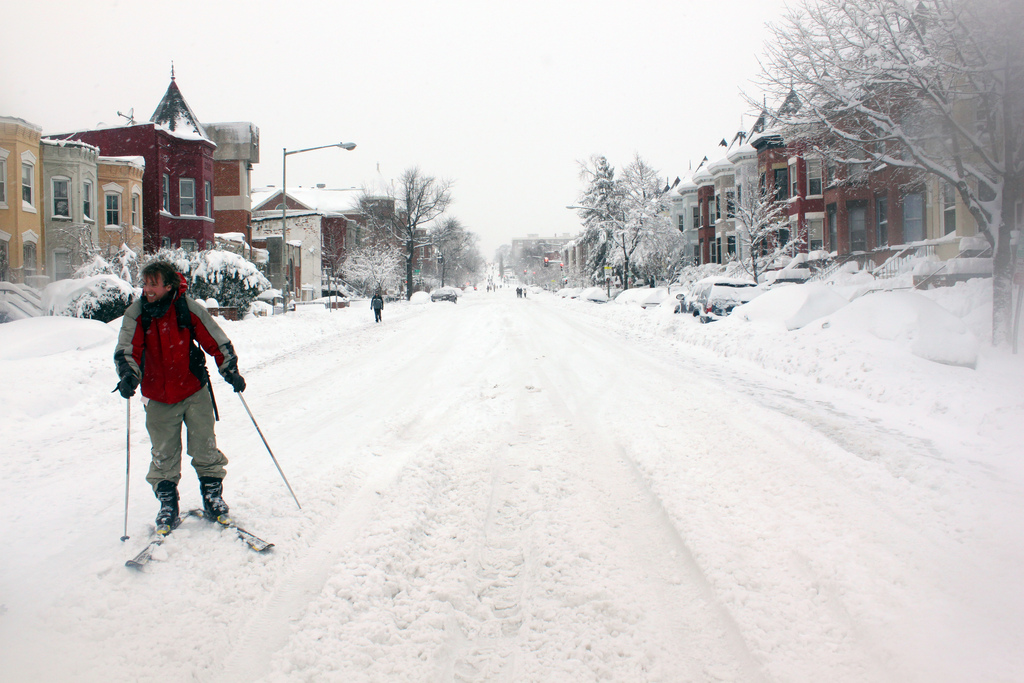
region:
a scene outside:
[6, 0, 1022, 655]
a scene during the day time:
[10, 12, 1020, 674]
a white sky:
[3, 1, 1021, 274]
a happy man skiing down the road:
[74, 240, 334, 624]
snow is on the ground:
[3, 282, 1022, 679]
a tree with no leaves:
[724, 1, 1022, 379]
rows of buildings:
[10, 51, 1016, 349]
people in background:
[313, 234, 590, 337]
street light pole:
[247, 111, 375, 343]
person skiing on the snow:
[72, 253, 297, 577]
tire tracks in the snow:
[557, 279, 969, 641]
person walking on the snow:
[361, 281, 387, 320]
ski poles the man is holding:
[119, 384, 304, 517]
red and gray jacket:
[108, 298, 239, 391]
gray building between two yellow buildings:
[0, 111, 153, 302]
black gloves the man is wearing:
[116, 361, 246, 404]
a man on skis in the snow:
[99, 250, 296, 571]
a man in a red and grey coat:
[105, 260, 248, 398]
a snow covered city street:
[133, 228, 1012, 656]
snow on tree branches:
[743, 15, 1016, 238]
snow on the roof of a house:
[140, 64, 213, 145]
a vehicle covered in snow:
[677, 279, 758, 336]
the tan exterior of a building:
[1, 120, 47, 298]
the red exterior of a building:
[144, 132, 214, 265]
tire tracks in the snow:
[229, 416, 787, 677]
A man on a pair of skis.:
[97, 258, 301, 576]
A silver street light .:
[280, 131, 361, 284]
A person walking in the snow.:
[369, 287, 386, 326]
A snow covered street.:
[309, 295, 753, 650]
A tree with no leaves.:
[770, 2, 1023, 360]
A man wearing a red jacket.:
[116, 252, 235, 404]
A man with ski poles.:
[112, 254, 306, 550]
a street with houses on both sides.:
[14, 3, 1020, 674]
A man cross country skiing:
[116, 261, 307, 575]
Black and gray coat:
[120, 296, 248, 398]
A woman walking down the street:
[368, 289, 391, 318]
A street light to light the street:
[280, 141, 358, 318]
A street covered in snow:
[8, 281, 1017, 664]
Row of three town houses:
[2, 123, 149, 292]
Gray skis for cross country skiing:
[125, 384, 315, 530]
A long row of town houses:
[570, 66, 1008, 286]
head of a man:
[144, 262, 174, 295]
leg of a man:
[152, 396, 181, 515]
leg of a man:
[184, 400, 230, 512]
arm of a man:
[187, 305, 242, 383]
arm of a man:
[117, 302, 141, 389]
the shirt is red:
[134, 311, 199, 398]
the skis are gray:
[117, 508, 264, 573]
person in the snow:
[373, 284, 380, 319]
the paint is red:
[751, 107, 900, 263]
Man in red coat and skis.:
[74, 251, 306, 577]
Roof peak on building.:
[146, 55, 208, 142]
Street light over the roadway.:
[270, 137, 360, 305]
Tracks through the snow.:
[261, 327, 730, 679]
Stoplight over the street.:
[533, 248, 569, 288]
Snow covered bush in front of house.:
[33, 260, 132, 324]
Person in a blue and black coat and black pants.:
[364, 282, 388, 327]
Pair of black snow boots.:
[147, 479, 234, 524]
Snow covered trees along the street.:
[569, 143, 690, 293]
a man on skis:
[81, 242, 290, 587]